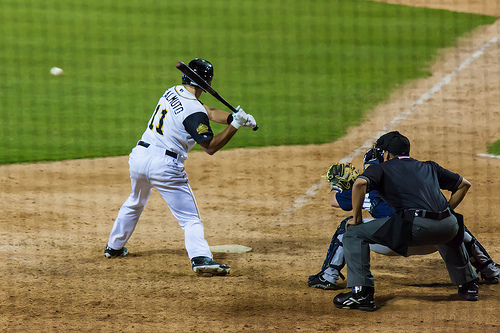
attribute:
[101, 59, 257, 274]
player — eleven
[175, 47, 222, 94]
helmet — black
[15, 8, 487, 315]
field — short, green, grassy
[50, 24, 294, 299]
man — batter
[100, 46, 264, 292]
player — focused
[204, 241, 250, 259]
object — hexagon shaped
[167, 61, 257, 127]
bat — black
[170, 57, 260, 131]
bat — black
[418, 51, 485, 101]
line — chalk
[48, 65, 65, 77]
baseball — thrown 